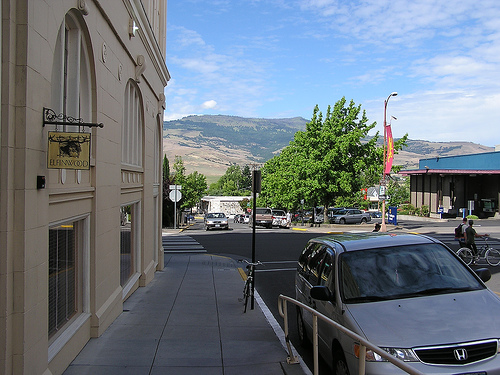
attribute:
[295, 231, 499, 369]
car — silver, parked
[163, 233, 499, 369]
road — for city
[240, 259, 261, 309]
bicycle — leaning, chained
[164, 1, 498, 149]
sky — blue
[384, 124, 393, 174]
banner — hanging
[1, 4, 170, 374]
building — tan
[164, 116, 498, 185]
mountain — brown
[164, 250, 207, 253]
line — white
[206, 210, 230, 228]
car — stopped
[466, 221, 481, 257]
person — walking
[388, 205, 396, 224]
mail box — blue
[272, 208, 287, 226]
vehicle — white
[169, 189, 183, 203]
sign — hexagonal, distant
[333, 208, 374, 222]
car — parked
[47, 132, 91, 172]
sign — yellow, hanging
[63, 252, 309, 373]
sidewalk — gray